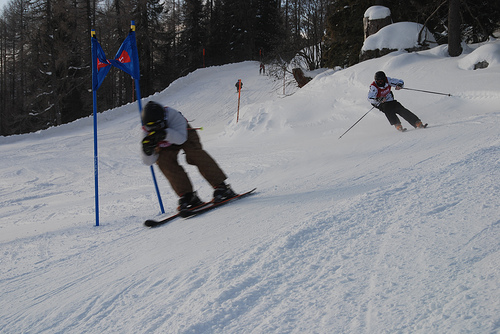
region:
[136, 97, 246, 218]
skier racing down jill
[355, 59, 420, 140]
skier racing down jill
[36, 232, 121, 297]
white snow on hill side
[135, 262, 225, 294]
white snow on hill side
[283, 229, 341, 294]
white snow on hill side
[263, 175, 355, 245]
white snow on hill side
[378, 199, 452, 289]
white snow on hill side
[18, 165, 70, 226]
white snow on hill side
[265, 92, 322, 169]
white snow on hill side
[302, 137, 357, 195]
white snow on hill side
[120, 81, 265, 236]
person on a pair of skiis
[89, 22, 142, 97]
blue and red flag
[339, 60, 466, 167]
person downhill skiing in the snow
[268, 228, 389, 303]
track in the snow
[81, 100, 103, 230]
blue pole holding the flag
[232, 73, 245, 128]
orange sign in the snow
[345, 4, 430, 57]
snow covered bolders near the woods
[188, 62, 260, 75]
hill of white fluffy snow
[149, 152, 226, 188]
brown pants the person is wearing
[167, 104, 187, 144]
part of the white shirt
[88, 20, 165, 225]
marker for competition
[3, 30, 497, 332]
tricky landscape to practice on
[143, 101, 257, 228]
person going very fast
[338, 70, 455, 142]
making a very fast turn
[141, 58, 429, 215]
four people close together on slope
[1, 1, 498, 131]
trees line the slopes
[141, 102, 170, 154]
snow gear to protect against snow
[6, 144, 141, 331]
ski tracks from other people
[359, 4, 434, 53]
shows depth of snow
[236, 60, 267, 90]
people trying to catch up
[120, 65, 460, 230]
skiers on a slope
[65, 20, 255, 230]
blue flags and poles next to skier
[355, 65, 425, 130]
skier leaning to side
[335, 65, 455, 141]
poles flared out to sides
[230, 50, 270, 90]
people on separate slope in distance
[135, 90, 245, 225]
skier leaning into raised hands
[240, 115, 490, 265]
smooth snow next to rough snow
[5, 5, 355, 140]
trees at top of slopes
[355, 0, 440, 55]
domes of snow over buildings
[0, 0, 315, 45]
streaks of sky through dense branches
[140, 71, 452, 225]
Two people are skiing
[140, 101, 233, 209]
The person is bent over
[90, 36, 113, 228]
The flag is blue and red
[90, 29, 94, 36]
Top of the flag is yellow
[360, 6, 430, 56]
Rocks covered with snow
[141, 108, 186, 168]
The jacket is white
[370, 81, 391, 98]
The vest is red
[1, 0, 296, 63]
There are some trees in the background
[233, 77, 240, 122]
Sign sticking out from the snow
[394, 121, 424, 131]
The boots are yellow